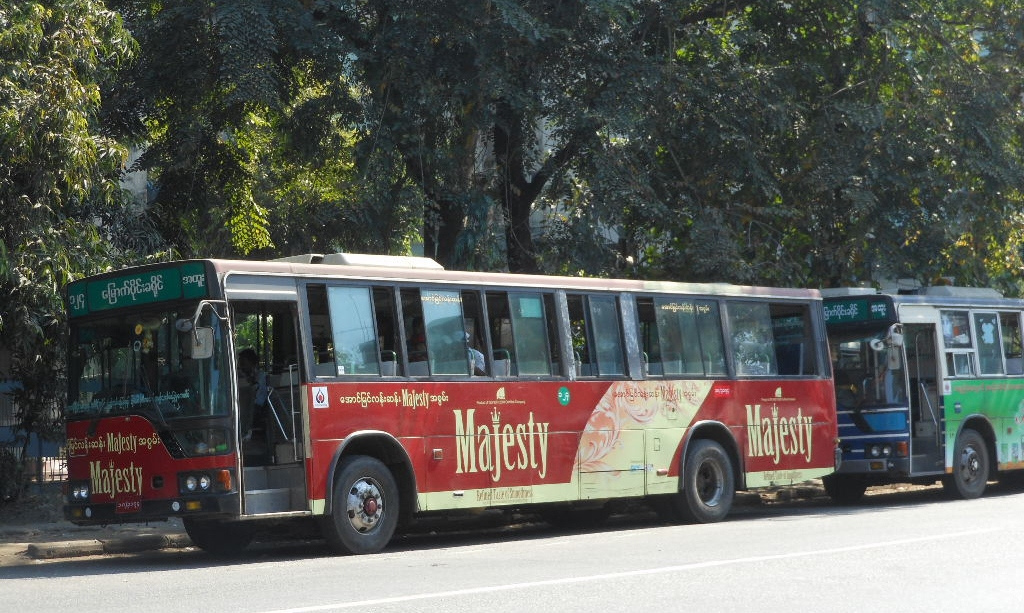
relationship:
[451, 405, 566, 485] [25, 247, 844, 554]
logo on passenger bus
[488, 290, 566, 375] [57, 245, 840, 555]
window on bus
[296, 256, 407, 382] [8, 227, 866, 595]
window on bus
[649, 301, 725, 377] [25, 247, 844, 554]
window of passenger bus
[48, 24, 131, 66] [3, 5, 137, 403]
leaves in trees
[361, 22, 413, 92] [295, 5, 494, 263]
leaves in trees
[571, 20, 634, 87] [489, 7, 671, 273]
leaves in trees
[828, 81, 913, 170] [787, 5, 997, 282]
leaves in trees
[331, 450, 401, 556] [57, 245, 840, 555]
tire on bus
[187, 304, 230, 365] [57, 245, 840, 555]
mirror on bus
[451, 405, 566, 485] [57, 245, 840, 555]
logo on bus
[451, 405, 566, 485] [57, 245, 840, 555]
logo on a bus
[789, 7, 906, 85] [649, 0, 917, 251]
leaves in tree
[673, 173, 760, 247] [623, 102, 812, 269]
leaves in tree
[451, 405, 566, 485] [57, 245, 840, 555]
logo on side of bus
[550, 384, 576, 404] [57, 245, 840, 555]
sticker on side of bus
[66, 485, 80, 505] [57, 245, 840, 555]
headlight on front of bus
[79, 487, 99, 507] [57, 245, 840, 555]
headlight on front of bus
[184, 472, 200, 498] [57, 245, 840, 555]
headlight on front of bus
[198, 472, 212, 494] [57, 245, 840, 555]
headlight on front of bus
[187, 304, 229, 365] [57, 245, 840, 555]
mirror front of bus